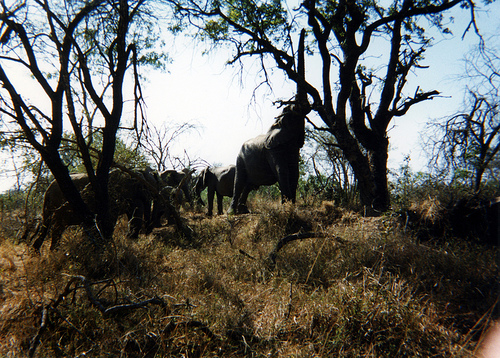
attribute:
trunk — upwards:
[271, 37, 320, 132]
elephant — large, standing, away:
[182, 51, 375, 233]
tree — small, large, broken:
[261, 30, 428, 215]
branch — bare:
[223, 12, 420, 94]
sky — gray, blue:
[163, 49, 208, 117]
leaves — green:
[232, 6, 306, 58]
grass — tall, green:
[185, 199, 354, 289]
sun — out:
[175, 45, 253, 134]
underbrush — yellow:
[285, 165, 449, 278]